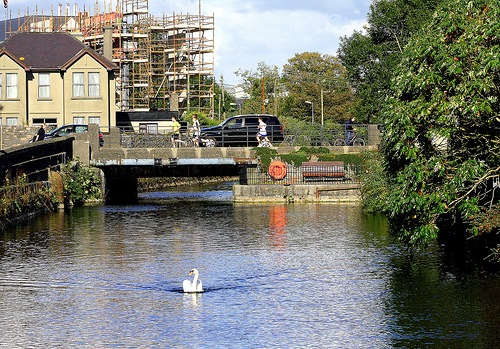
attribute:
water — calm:
[0, 206, 498, 346]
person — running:
[253, 117, 268, 144]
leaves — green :
[386, 59, 491, 149]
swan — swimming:
[136, 248, 254, 323]